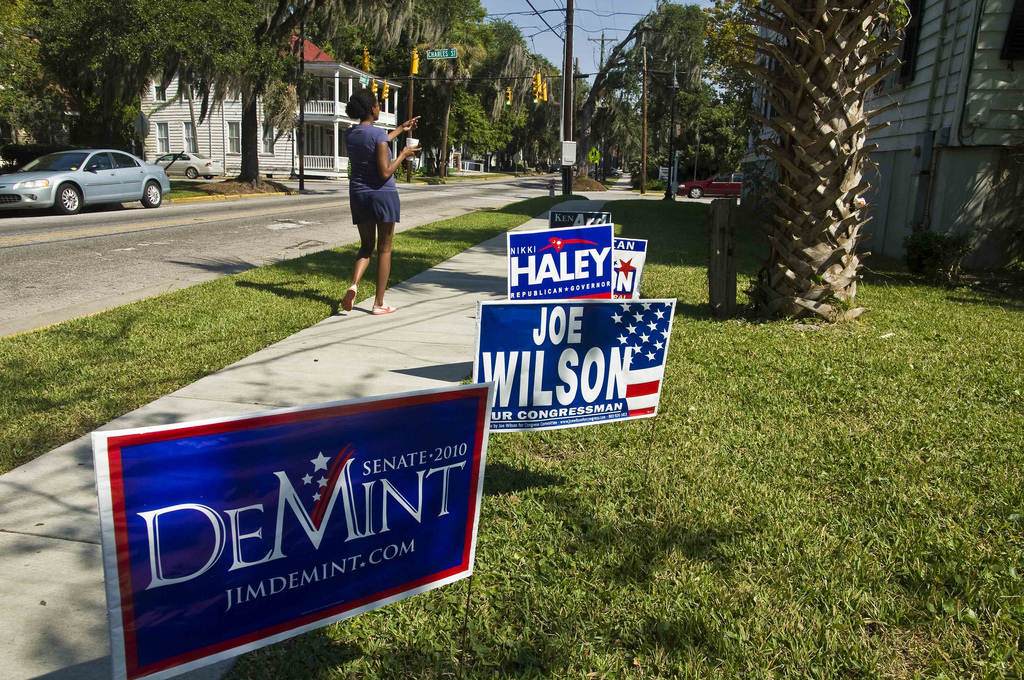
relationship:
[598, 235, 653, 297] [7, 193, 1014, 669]
sign stuck in ground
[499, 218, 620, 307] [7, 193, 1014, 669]
sign stuck in ground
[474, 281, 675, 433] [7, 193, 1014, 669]
sign stuck in ground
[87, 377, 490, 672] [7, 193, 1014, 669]
sign stuck in ground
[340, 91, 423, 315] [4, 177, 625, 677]
woman walking down sidewalk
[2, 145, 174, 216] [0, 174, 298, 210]
car parked beside curb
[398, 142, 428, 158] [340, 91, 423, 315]
hand part of woman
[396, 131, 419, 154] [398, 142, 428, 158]
cup held in hand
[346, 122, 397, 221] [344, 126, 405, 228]
woman wearing clothing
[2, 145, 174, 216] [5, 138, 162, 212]
car in street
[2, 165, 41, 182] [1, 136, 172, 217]
headlight of car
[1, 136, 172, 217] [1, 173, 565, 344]
car in street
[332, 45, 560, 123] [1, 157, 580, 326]
lights above street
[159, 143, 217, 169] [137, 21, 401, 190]
car parked in front of building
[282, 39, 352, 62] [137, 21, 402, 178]
roof above building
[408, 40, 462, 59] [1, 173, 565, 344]
sign above street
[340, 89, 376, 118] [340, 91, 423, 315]
hair on woman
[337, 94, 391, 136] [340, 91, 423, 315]
head on woman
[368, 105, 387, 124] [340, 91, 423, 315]
face on woman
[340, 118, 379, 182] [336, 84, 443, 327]
torso on woman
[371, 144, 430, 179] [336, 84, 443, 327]
arm on woman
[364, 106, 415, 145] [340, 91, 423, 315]
arm on woman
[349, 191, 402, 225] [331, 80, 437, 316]
shorts on woman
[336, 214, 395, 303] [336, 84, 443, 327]
legs on woman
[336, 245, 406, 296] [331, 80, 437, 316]
calves on woman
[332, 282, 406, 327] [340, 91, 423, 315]
shoes on woman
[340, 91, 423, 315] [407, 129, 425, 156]
woman holding cup